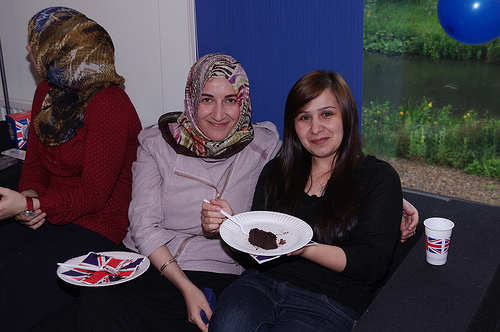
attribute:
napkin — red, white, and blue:
[65, 255, 139, 281]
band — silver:
[159, 258, 178, 273]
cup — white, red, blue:
[419, 211, 459, 268]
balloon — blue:
[430, 5, 498, 62]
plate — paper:
[52, 237, 156, 304]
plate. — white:
[208, 179, 324, 284]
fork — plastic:
[202, 194, 252, 231]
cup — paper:
[424, 214, 454, 267]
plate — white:
[208, 196, 345, 264]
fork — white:
[195, 195, 253, 234]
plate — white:
[218, 209, 315, 260]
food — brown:
[247, 225, 288, 253]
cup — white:
[420, 214, 456, 270]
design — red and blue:
[425, 234, 454, 255]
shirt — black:
[241, 149, 401, 309]